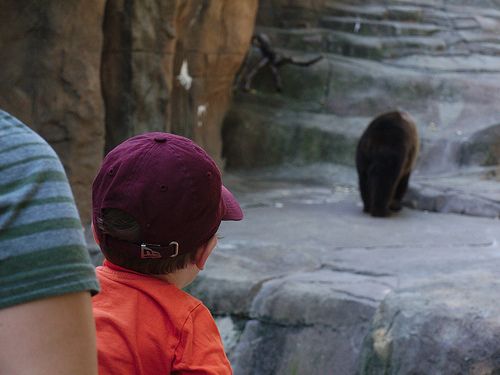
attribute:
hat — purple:
[89, 132, 244, 259]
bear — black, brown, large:
[354, 112, 418, 217]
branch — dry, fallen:
[234, 33, 324, 95]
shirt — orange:
[92, 260, 234, 374]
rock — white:
[1, 0, 261, 222]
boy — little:
[91, 131, 246, 373]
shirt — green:
[1, 108, 103, 309]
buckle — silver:
[139, 242, 181, 258]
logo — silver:
[140, 243, 164, 259]